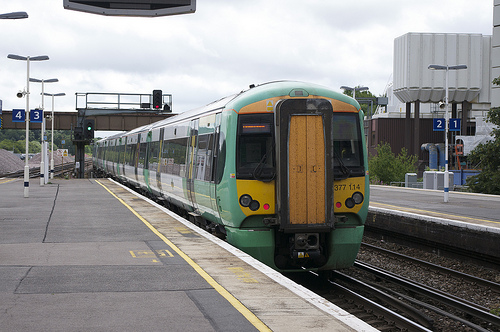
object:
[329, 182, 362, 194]
numbers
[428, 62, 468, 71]
light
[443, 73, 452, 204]
pole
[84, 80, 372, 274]
train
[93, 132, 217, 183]
windows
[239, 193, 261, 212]
light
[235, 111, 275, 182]
window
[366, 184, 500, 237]
platform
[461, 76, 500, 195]
tree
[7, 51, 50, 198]
light pole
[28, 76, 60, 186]
light pole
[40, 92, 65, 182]
light pole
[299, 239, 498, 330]
train tracks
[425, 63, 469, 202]
light pole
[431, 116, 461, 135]
signs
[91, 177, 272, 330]
stripe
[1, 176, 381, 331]
platform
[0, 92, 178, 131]
bridge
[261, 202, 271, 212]
light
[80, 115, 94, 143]
traffic signal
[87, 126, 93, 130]
light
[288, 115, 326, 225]
door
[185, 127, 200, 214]
door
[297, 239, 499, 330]
rails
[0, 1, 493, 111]
cloud